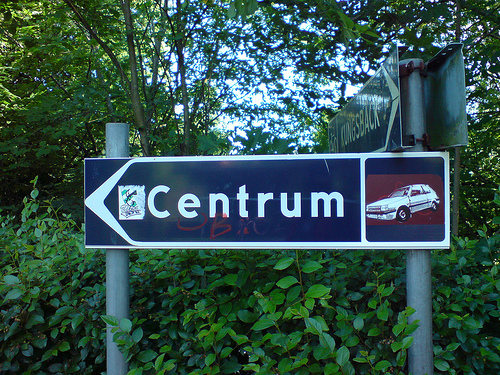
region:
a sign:
[189, 136, 327, 291]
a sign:
[150, 99, 307, 359]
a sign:
[174, 90, 347, 237]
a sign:
[233, 193, 376, 364]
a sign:
[210, 162, 290, 332]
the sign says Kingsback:
[312, 31, 485, 158]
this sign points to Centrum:
[91, 157, 443, 250]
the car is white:
[353, 175, 443, 237]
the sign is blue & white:
[82, 153, 472, 268]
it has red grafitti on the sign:
[161, 194, 266, 257]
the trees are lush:
[35, 20, 176, 95]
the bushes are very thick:
[163, 265, 382, 359]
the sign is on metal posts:
[53, 102, 467, 370]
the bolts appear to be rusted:
[400, 50, 449, 152]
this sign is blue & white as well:
[321, 59, 423, 155]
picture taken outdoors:
[60, 110, 378, 367]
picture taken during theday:
[43, 120, 434, 372]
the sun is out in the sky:
[45, 91, 460, 337]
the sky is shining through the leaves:
[42, 81, 383, 157]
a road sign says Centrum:
[62, 130, 495, 280]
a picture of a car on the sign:
[55, 107, 497, 277]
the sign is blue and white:
[72, 130, 489, 314]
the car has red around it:
[91, 143, 498, 305]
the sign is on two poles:
[70, 137, 479, 306]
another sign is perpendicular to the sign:
[50, 109, 455, 219]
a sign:
[210, 110, 350, 366]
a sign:
[226, 38, 406, 368]